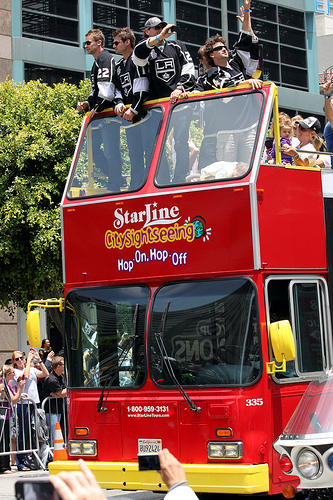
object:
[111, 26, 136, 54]
hand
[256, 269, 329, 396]
window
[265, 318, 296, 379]
mirror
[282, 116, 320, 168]
woman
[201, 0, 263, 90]
man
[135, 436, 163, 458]
license plate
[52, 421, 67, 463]
cone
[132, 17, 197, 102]
football player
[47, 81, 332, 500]
bus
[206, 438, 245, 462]
headlight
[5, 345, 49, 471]
man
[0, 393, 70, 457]
baracade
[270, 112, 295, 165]
baby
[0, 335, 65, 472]
crowd